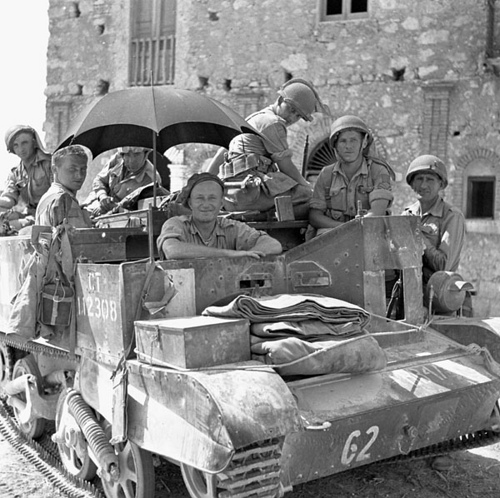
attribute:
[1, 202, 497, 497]
tank — grey